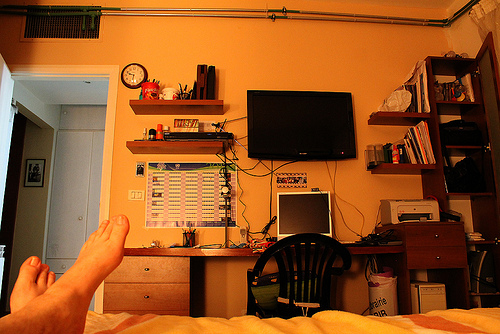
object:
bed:
[0, 303, 500, 332]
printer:
[379, 199, 441, 226]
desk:
[378, 220, 473, 314]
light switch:
[126, 189, 145, 201]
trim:
[7, 63, 123, 322]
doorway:
[0, 62, 114, 74]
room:
[0, 0, 500, 333]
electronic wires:
[260, 158, 279, 239]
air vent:
[20, 5, 101, 38]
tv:
[244, 90, 360, 160]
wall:
[0, 15, 455, 248]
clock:
[117, 62, 150, 90]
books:
[363, 143, 377, 165]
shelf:
[364, 123, 442, 175]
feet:
[18, 212, 130, 333]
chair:
[244, 218, 353, 322]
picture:
[23, 156, 47, 187]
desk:
[103, 243, 406, 322]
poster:
[145, 160, 237, 229]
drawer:
[102, 255, 191, 283]